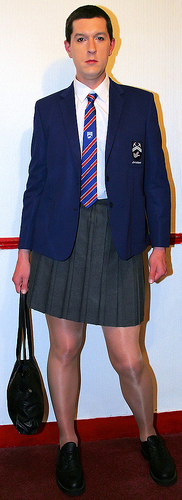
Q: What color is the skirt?
A: Black.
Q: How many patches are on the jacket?
A: One.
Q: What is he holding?
A: A purse.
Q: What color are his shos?
A: Black.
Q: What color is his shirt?
A: White.